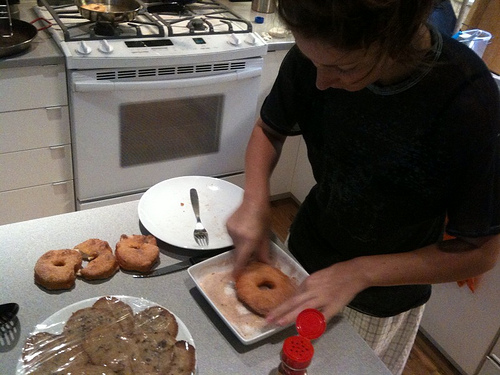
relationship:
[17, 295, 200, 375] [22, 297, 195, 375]
plate covered by cookies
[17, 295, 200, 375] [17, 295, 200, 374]
plate wrapped in plastic wrap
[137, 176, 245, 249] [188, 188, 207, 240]
plate with fork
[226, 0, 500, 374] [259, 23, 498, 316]
woman wearing shirt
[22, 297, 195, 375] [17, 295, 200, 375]
cookies on plate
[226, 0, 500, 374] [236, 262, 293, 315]
woman coating donut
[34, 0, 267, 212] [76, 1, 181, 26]
stove with skillet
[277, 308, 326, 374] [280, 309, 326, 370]
seasoning with shaker top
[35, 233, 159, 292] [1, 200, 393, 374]
donuts on counter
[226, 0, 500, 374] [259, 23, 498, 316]
woman with shirt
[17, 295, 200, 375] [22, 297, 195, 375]
plate of cookies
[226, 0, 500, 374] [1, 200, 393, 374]
woman standing by counter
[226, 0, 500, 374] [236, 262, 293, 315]
woman holding donut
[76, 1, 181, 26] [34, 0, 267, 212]
skillet on stove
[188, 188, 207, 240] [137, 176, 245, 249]
fork on plate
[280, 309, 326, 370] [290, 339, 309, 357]
shaker top has holes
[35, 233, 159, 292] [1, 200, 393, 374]
donuts sitting on counter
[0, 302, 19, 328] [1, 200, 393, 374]
spatula on counter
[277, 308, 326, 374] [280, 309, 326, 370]
seasoning has shaker top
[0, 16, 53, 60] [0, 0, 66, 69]
pan on counter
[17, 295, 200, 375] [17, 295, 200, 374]
plate covered with plastic wrap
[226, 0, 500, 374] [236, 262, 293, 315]
woman working with donut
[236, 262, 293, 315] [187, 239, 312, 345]
donut in dish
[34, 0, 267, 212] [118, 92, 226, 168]
stove with window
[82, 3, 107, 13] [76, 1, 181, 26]
donut in skillet